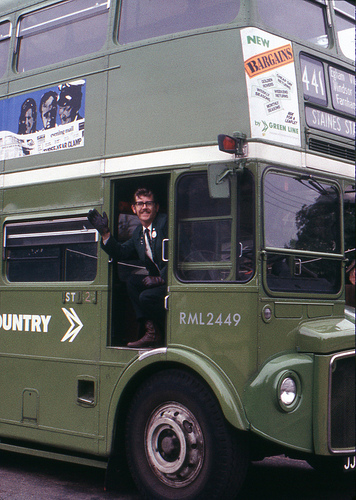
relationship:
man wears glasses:
[92, 189, 166, 345] [132, 200, 153, 207]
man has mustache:
[92, 189, 166, 345] [138, 206, 152, 214]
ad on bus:
[0, 74, 85, 165] [1, 4, 354, 475]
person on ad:
[58, 79, 87, 148] [0, 74, 85, 165]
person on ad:
[39, 90, 58, 155] [0, 74, 85, 165]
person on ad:
[19, 100, 38, 159] [0, 74, 85, 165]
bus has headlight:
[1, 4, 354, 475] [275, 371, 298, 407]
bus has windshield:
[1, 4, 354, 475] [259, 165, 342, 296]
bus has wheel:
[1, 4, 354, 475] [131, 371, 233, 492]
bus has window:
[1, 4, 354, 475] [264, 169, 340, 289]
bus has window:
[1, 4, 354, 475] [178, 174, 251, 276]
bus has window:
[1, 4, 354, 475] [8, 227, 95, 279]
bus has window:
[1, 4, 354, 475] [117, 6, 248, 36]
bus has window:
[1, 4, 354, 475] [14, 15, 108, 55]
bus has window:
[1, 4, 354, 475] [252, 5, 331, 46]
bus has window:
[1, 4, 354, 475] [0, 24, 12, 78]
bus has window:
[1, 4, 354, 475] [329, 10, 354, 62]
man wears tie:
[92, 189, 166, 345] [147, 227, 151, 257]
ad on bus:
[240, 28, 303, 146] [1, 4, 354, 475]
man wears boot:
[92, 189, 166, 345] [125, 323, 157, 346]